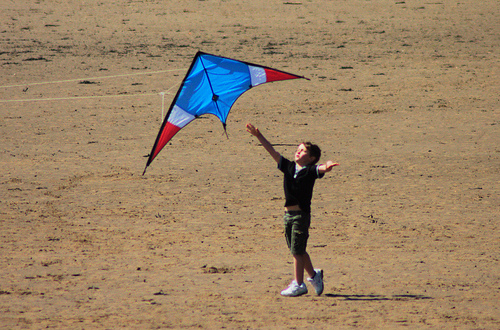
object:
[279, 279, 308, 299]
shoe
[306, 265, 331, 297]
shoe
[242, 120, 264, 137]
hand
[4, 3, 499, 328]
dirt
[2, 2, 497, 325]
ground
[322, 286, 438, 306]
shadow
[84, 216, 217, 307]
dirt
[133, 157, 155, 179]
spoke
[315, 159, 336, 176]
arm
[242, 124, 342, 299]
boy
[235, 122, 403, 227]
kid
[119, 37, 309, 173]
kite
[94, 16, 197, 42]
air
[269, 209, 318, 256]
shorts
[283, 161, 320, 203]
shirt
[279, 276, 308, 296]
foot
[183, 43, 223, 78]
part